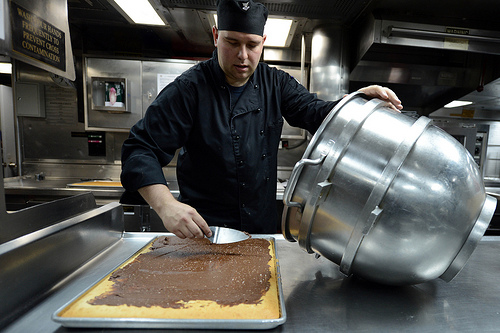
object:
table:
[0, 218, 500, 333]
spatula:
[195, 226, 250, 244]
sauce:
[96, 237, 269, 303]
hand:
[157, 199, 216, 239]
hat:
[215, 0, 268, 37]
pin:
[238, 0, 252, 12]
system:
[360, 22, 499, 71]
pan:
[0, 188, 91, 216]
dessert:
[75, 179, 123, 187]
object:
[88, 131, 107, 157]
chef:
[120, 0, 406, 239]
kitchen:
[0, 0, 500, 333]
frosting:
[80, 234, 287, 312]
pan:
[65, 176, 124, 188]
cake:
[57, 232, 278, 322]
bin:
[285, 92, 499, 283]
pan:
[53, 234, 290, 322]